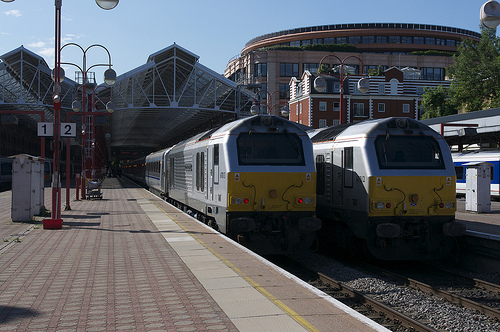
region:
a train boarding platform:
[8, 180, 360, 327]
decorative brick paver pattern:
[0, 179, 224, 330]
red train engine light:
[240, 197, 247, 205]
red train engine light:
[294, 196, 303, 203]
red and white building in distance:
[282, 68, 444, 128]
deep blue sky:
[5, 2, 488, 70]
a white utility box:
[8, 149, 45, 224]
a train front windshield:
[235, 129, 306, 168]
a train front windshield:
[372, 133, 442, 168]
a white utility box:
[462, 159, 493, 213]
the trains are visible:
[283, 142, 496, 273]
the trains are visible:
[147, 96, 370, 256]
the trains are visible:
[268, 88, 486, 236]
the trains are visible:
[174, 45, 462, 222]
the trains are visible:
[265, 180, 420, 305]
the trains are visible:
[200, 51, 348, 307]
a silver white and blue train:
[143, 113, 319, 233]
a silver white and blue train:
[294, 119, 454, 240]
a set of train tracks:
[298, 239, 494, 327]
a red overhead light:
[0, 1, 126, 236]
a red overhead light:
[52, 36, 117, 213]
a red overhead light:
[309, 54, 369, 126]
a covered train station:
[0, 39, 269, 181]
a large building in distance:
[226, 19, 487, 102]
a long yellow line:
[131, 179, 314, 330]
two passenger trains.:
[153, 122, 469, 255]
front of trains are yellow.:
[228, 172, 460, 214]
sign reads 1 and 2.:
[41, 115, 86, 142]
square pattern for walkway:
[63, 254, 173, 324]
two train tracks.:
[329, 259, 499, 329]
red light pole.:
[40, 3, 80, 237]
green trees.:
[436, 36, 496, 123]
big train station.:
[35, 62, 237, 189]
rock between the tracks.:
[295, 239, 497, 325]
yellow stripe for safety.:
[140, 198, 270, 315]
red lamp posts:
[46, 1, 65, 231]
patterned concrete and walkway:
[27, 223, 272, 330]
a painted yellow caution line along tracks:
[164, 182, 321, 329]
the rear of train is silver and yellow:
[214, 111, 464, 238]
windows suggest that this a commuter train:
[116, 138, 234, 203]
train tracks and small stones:
[281, 246, 498, 330]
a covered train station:
[0, 45, 250, 117]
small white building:
[458, 151, 496, 219]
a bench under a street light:
[76, 164, 107, 203]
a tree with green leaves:
[416, 16, 499, 113]